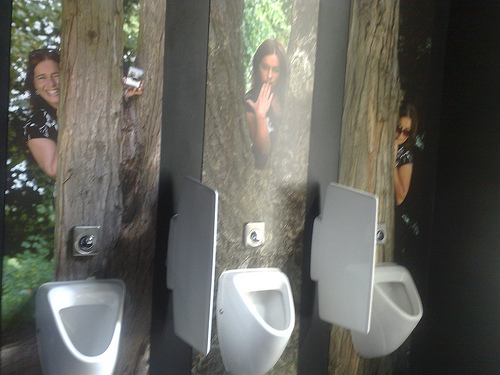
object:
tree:
[327, 0, 404, 375]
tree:
[189, 0, 319, 375]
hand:
[122, 76, 144, 101]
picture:
[124, 65, 145, 89]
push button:
[77, 233, 96, 251]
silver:
[86, 233, 97, 242]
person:
[241, 38, 288, 170]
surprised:
[256, 54, 282, 91]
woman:
[390, 98, 421, 208]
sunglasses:
[396, 127, 413, 137]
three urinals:
[33, 262, 429, 375]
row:
[31, 258, 429, 372]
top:
[35, 275, 127, 313]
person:
[22, 48, 61, 181]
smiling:
[35, 70, 61, 104]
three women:
[23, 36, 423, 207]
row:
[21, 38, 419, 207]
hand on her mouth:
[245, 80, 276, 115]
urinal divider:
[164, 176, 221, 356]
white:
[183, 284, 203, 328]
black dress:
[21, 100, 59, 144]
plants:
[13, 37, 30, 51]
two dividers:
[161, 176, 384, 359]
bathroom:
[0, 0, 500, 375]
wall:
[0, 0, 447, 373]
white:
[95, 357, 111, 368]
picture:
[0, 0, 453, 375]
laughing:
[256, 53, 283, 92]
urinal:
[29, 275, 131, 375]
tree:
[52, 0, 167, 375]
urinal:
[214, 264, 297, 374]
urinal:
[350, 261, 426, 360]